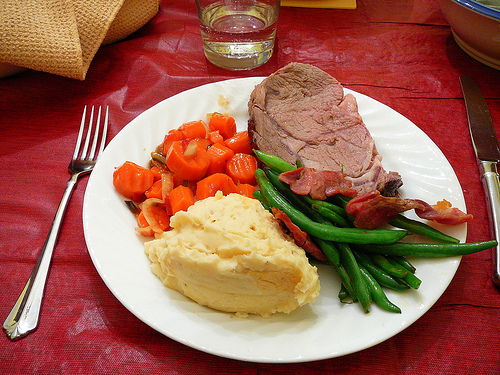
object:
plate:
[82, 76, 467, 363]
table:
[0, 0, 499, 374]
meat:
[246, 61, 401, 197]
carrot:
[112, 112, 257, 234]